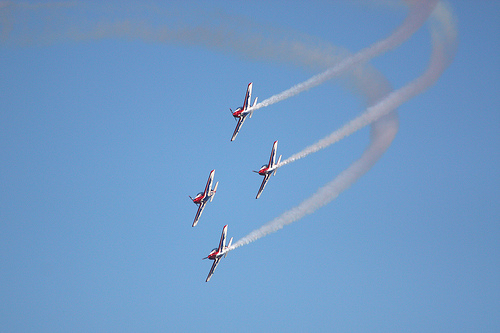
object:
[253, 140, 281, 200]
plane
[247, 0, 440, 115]
trail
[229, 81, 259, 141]
airplane